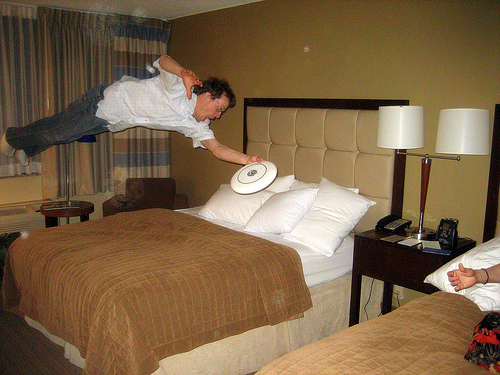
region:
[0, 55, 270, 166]
Man leaping to catch frisbee above a bed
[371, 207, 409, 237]
Black telephone on bedside table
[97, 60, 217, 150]
White shirt on man with frisbee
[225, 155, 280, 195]
White frisbee held by a man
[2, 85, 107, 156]
Gray jeans on man with frisbee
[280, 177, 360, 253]
white pillow on bed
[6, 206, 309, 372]
Brown bedspread on bed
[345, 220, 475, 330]
Brown, wood bedside table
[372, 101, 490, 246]
Double white-shaded, brown lamp on bedside table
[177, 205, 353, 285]
White bed sheet on bed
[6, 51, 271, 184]
Man is in the air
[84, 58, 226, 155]
Man is wearing a white dress shirt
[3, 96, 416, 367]
A bed is in the foreground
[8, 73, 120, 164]
Man is wearing jeans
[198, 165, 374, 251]
A pile of white pillows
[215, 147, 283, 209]
Flying disc is white in color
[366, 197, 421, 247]
A black home phone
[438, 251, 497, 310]
A hand is in the foreground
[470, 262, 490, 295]
Person has a black wristband around arm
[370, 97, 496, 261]
A double lamp in the foreground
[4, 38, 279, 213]
The man is airborne.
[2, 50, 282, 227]
The man is holding a frisbee.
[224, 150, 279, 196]
The frisbee is white.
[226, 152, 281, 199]
The frisbee is round.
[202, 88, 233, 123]
The man is wearing glasses.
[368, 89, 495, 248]
The lamp has two shades.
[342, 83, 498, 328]
The lamp in on a bedside table.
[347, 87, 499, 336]
Telephone on bedside table.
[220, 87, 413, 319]
The bed has a padded headboard.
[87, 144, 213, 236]
Brown chair in corner of room.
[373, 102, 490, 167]
two white lamp shades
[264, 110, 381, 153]
beige headboard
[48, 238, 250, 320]
brown bedspread with a square pattern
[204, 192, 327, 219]
white pillows on a hotel bed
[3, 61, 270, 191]
man with a frisbee in midair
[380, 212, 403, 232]
black and silver telephone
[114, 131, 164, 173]
blue and brown striped curtains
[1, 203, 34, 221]
air conditioner unit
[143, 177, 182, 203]
brown armchair in the corner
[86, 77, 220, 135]
man wearing a white shirt and jeans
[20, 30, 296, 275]
man catching a white frisbee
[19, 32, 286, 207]
man in the air catching a white frisbee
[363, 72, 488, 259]
lamp on a bedside table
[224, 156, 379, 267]
white pillows on a bed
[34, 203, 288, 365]
brown comforter on a bed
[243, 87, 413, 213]
beige and brown bed headboard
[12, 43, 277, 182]
man wearing a white long sleeved shirt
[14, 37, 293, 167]
man wearing blue jeans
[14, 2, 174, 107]
brown beige and blue curtains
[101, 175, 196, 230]
brown chair on a hotel room